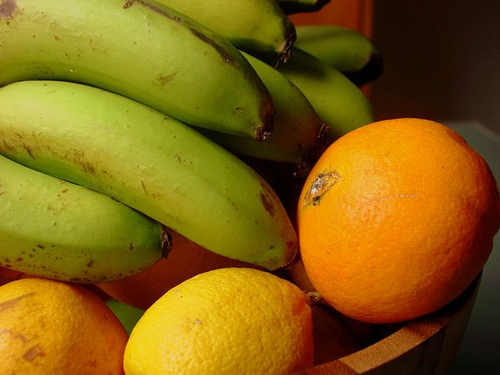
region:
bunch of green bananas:
[6, 3, 369, 275]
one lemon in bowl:
[122, 269, 304, 374]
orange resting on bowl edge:
[298, 108, 483, 310]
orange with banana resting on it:
[5, 278, 122, 374]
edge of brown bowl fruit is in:
[207, 257, 482, 374]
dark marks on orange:
[0, 285, 95, 374]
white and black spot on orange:
[299, 168, 341, 213]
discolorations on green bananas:
[6, 2, 286, 267]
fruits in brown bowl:
[6, 5, 494, 374]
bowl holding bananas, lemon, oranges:
[7, 16, 484, 366]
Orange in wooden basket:
[292, 116, 496, 327]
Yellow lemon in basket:
[118, 262, 316, 373]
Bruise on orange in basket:
[296, 165, 346, 211]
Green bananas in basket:
[0, 0, 382, 293]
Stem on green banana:
[148, 226, 179, 262]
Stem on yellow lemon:
[295, 281, 328, 314]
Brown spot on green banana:
[241, 171, 294, 223]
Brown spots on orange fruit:
[0, 286, 57, 370]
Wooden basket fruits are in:
[285, 282, 463, 374]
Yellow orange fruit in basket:
[0, 266, 132, 373]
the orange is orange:
[304, 127, 481, 369]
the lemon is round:
[117, 229, 304, 374]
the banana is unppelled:
[20, 182, 168, 267]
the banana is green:
[51, 123, 313, 276]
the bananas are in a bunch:
[43, 13, 322, 276]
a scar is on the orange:
[301, 165, 374, 224]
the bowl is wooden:
[343, 325, 413, 373]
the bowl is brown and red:
[328, 345, 399, 372]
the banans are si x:
[1, 3, 336, 249]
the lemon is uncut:
[163, 277, 281, 372]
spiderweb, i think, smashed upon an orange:
[298, 157, 349, 213]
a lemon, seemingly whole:
[116, 265, 318, 372]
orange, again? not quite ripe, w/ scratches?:
[1, 278, 135, 373]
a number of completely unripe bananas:
[0, 0, 376, 299]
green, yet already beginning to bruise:
[0, 0, 240, 77]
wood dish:
[291, 277, 482, 372]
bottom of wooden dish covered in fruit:
[43, 273, 480, 373]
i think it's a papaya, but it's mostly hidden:
[84, 209, 271, 313]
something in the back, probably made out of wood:
[249, 2, 379, 147]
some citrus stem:
[300, 286, 325, 307]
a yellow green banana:
[2, 82, 297, 272]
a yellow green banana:
[0, 153, 170, 279]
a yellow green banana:
[0, 1, 275, 145]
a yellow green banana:
[162, 0, 299, 66]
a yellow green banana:
[215, 47, 326, 170]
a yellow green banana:
[275, 44, 373, 133]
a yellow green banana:
[290, 25, 373, 75]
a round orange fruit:
[297, 117, 492, 326]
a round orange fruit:
[0, 276, 128, 373]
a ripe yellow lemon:
[122, 269, 312, 374]